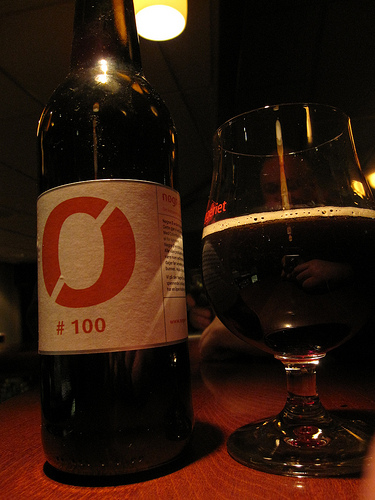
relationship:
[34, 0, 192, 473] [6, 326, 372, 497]
bottle on table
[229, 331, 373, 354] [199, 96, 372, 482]
bottom of glass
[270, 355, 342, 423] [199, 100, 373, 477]
stem of wine glass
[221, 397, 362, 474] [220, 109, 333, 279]
base of glass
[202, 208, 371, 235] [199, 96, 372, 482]
foam in glass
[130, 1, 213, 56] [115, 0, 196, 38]
light in lampshade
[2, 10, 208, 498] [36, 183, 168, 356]
bottle with number